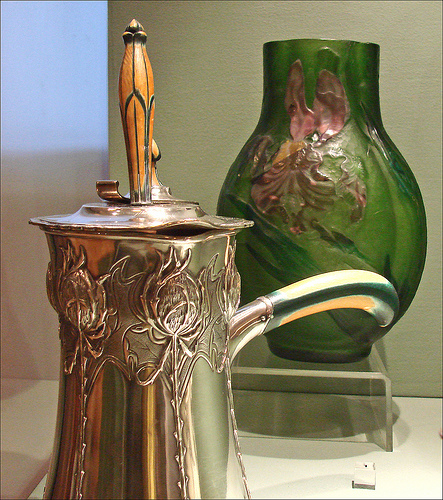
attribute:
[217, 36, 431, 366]
vase — green, brown, green lined, see through, ceramic, glass, large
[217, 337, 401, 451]
display — transparant, clear, glass, large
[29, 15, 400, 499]
canister — long, metal, in the front, gold colored, decorative, gold surfaced, black lined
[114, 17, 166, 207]
handle — wooden, wood, black, gold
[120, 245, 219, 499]
foral design — metal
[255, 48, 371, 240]
glass design — brown, pink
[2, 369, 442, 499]
display table — white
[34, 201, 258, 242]
top — metal, bronze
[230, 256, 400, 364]
spout — curved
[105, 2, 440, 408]
wall — smooth, light green, soft brown, green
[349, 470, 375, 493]
clip — plastic, white